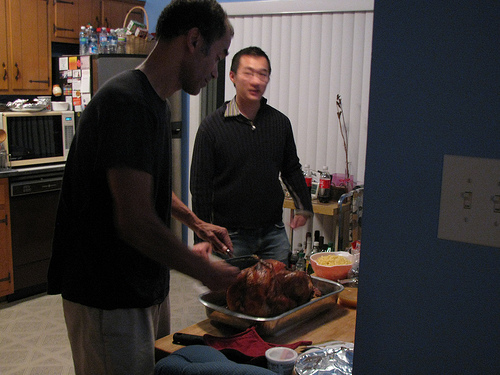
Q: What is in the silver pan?
A: Turkey.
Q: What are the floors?
A: Grey and beige.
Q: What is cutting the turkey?
A: The man.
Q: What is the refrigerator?
A: Black and silver.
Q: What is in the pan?
A: Roasted turkey.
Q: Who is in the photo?
A: Two men.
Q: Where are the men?
A: In the kitchen.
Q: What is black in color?
A: The shirt.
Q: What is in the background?
A: Curtains.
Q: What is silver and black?
A: The fridge.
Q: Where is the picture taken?
A: In a kitchen.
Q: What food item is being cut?
A: Turkey.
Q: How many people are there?
A: Two.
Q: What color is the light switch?
A: White.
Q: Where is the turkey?
A: In a pan.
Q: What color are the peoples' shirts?
A: Black.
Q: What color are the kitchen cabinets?
A: Brown.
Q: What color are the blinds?
A: White.